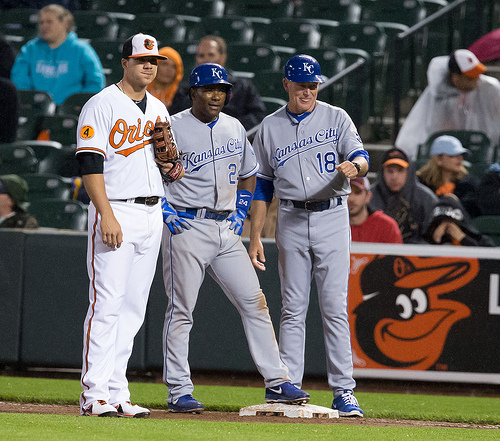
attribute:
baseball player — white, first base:
[68, 32, 184, 418]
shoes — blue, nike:
[157, 384, 311, 415]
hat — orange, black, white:
[444, 48, 489, 81]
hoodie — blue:
[11, 40, 104, 102]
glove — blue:
[228, 188, 250, 235]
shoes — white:
[78, 397, 152, 417]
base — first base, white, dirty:
[232, 396, 342, 423]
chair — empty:
[263, 20, 322, 48]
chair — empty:
[125, 15, 186, 39]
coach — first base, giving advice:
[246, 48, 365, 421]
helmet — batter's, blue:
[190, 61, 236, 89]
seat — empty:
[190, 15, 252, 42]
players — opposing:
[72, 34, 369, 421]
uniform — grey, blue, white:
[152, 109, 287, 399]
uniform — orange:
[75, 82, 174, 404]